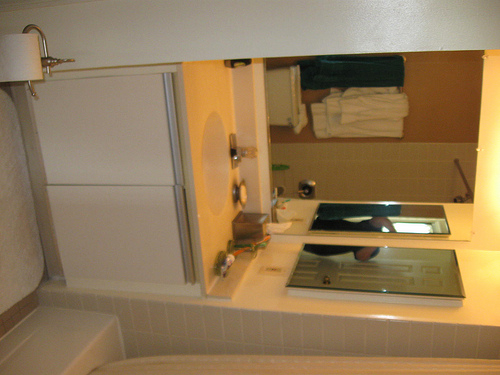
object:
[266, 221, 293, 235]
tissue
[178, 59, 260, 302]
sink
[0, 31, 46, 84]
toilet paper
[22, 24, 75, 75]
holder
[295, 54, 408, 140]
towels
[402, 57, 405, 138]
rod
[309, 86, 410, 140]
towels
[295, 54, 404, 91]
towel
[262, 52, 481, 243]
mirror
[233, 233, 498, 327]
wall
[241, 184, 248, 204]
soap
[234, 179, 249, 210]
soap dish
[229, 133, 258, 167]
faucet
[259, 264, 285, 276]
outlet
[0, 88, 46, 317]
rug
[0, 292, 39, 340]
floor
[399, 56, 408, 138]
rack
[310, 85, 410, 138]
towel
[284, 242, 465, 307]
cabinet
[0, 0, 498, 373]
bathroom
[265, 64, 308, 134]
garbage can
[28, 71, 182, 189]
door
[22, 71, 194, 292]
cabinet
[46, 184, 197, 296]
door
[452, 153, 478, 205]
shower curtain rod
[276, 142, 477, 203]
shower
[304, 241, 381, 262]
person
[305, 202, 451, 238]
reflection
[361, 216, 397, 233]
reflection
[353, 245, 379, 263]
arm